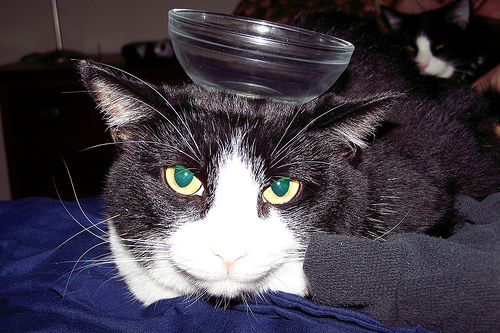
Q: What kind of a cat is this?
A: A black cat.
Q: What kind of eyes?
A: Green.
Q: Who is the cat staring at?
A: The person taking the picture.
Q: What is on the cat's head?
A: A bowl.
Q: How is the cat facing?
A: Straight ahead.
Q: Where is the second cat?
A: In the right background.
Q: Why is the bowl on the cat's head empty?
A: It's feeding time.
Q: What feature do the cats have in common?
A: A white face.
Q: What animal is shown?
A: A cat.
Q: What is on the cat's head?
A: A bowl.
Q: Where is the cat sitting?
A: A bed.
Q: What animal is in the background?
A: A cat.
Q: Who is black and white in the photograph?
A: Both cats.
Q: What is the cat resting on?
A: A blue towel.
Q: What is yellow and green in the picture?
A: Cat's eyes.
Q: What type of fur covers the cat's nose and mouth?
A: White.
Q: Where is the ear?
A: On the cat.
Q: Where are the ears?
A: On the cat.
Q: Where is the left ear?
A: On the cat.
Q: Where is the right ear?
A: On the cat.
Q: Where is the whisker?
A: On the cat.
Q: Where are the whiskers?
A: On the cat.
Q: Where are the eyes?
A: On the cat.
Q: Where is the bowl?
A: On the cat.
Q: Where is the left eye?
A: On the cat.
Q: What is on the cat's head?
A: Bowl.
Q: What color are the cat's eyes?
A: Yellow.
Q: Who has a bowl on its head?
A: Cat.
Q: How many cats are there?
A: 1.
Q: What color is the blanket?
A: Blue.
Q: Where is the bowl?
A: On the cat's head.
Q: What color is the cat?
A: Black and white.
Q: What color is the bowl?
A: Clear.